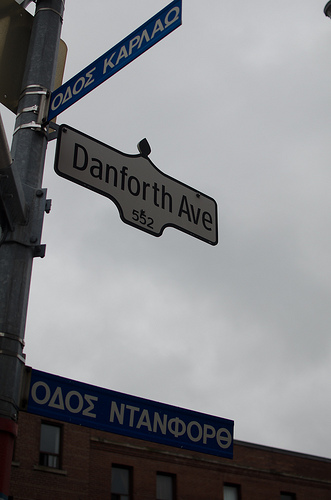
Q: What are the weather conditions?
A: It is clear.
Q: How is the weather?
A: It is clear.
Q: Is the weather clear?
A: Yes, it is clear.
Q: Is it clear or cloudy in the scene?
A: It is clear.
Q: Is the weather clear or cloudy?
A: It is clear.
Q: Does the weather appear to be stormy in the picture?
A: No, it is clear.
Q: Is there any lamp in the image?
A: No, there are no lamps.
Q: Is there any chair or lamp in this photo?
A: No, there are no lamps or chairs.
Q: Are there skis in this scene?
A: No, there are no skis.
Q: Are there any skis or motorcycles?
A: No, there are no skis or motorcycles.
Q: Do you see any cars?
A: No, there are no cars.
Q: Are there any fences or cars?
A: No, there are no cars or fences.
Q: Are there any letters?
A: Yes, there are letters.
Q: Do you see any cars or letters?
A: Yes, there are letters.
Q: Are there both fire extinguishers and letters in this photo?
A: No, there are letters but no fire extinguishers.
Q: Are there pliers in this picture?
A: No, there are no pliers.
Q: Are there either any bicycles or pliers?
A: No, there are no pliers or bicycles.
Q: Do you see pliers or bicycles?
A: No, there are no pliers or bicycles.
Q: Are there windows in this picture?
A: Yes, there is a window.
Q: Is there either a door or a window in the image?
A: Yes, there is a window.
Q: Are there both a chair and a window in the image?
A: No, there is a window but no chairs.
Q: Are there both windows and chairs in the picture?
A: No, there is a window but no chairs.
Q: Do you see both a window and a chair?
A: No, there is a window but no chairs.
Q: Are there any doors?
A: No, there are no doors.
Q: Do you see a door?
A: No, there are no doors.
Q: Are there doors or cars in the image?
A: No, there are no doors or cars.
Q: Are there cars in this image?
A: No, there are no cars.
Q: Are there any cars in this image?
A: No, there are no cars.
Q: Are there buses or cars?
A: No, there are no cars or buses.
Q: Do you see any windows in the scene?
A: Yes, there is a window.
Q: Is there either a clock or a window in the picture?
A: Yes, there is a window.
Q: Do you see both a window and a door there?
A: No, there is a window but no doors.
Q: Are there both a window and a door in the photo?
A: No, there is a window but no doors.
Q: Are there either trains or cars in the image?
A: No, there are no cars or trains.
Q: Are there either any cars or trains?
A: No, there are no cars or trains.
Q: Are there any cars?
A: No, there are no cars.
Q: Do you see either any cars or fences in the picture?
A: No, there are no cars or fences.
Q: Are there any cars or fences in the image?
A: No, there are no cars or fences.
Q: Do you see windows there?
A: Yes, there is a window.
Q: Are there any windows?
A: Yes, there is a window.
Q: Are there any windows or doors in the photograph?
A: Yes, there is a window.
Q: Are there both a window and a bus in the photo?
A: No, there is a window but no buses.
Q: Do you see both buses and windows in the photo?
A: No, there is a window but no buses.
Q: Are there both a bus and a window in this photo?
A: No, there is a window but no buses.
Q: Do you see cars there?
A: No, there are no cars.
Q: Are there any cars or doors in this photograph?
A: No, there are no cars or doors.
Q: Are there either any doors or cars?
A: No, there are no cars or doors.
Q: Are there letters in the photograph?
A: Yes, there are letters.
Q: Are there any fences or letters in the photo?
A: Yes, there are letters.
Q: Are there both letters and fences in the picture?
A: No, there are letters but no fences.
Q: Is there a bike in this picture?
A: No, there are no bikes.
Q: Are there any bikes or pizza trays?
A: No, there are no bikes or pizza trays.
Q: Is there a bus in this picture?
A: No, there are no buses.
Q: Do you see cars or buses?
A: No, there are no buses or cars.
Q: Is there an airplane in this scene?
A: No, there are no airplanes.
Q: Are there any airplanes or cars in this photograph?
A: No, there are no airplanes or cars.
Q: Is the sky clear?
A: Yes, the sky is clear.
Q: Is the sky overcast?
A: No, the sky is clear.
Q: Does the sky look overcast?
A: No, the sky is clear.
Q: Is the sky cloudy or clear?
A: The sky is clear.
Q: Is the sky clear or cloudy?
A: The sky is clear.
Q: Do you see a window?
A: Yes, there is a window.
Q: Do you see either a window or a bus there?
A: Yes, there is a window.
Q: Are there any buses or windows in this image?
A: Yes, there is a window.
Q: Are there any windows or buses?
A: Yes, there is a window.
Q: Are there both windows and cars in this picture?
A: No, there is a window but no cars.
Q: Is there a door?
A: No, there are no doors.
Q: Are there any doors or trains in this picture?
A: No, there are no doors or trains.